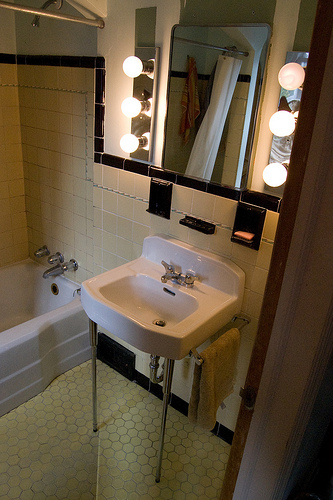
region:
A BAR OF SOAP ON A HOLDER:
[223, 220, 266, 250]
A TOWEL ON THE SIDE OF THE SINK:
[184, 321, 244, 438]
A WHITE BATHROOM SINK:
[75, 229, 263, 371]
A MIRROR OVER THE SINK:
[156, 15, 280, 194]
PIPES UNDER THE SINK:
[140, 349, 184, 389]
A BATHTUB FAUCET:
[26, 240, 84, 286]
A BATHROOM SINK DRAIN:
[148, 312, 170, 329]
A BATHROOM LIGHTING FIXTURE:
[114, 49, 161, 164]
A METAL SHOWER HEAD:
[26, 7, 52, 33]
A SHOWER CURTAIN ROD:
[4, 3, 113, 33]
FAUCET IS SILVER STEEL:
[153, 252, 207, 310]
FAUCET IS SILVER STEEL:
[146, 260, 194, 297]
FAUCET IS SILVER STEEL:
[150, 251, 202, 302]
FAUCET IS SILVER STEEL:
[141, 256, 219, 323]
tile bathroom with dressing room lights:
[5, 0, 327, 490]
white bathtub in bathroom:
[0, 248, 101, 417]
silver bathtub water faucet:
[26, 243, 84, 288]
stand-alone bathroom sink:
[79, 228, 255, 486]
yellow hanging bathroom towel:
[170, 312, 258, 468]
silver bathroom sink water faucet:
[155, 254, 200, 296]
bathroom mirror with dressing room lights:
[125, 8, 303, 203]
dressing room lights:
[117, 42, 319, 195]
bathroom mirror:
[152, 1, 275, 201]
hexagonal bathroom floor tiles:
[6, 419, 144, 497]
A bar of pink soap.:
[237, 227, 250, 244]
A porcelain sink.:
[79, 235, 232, 347]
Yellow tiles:
[45, 435, 101, 483]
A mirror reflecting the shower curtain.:
[174, 33, 252, 193]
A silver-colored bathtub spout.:
[41, 268, 55, 279]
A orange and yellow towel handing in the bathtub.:
[180, 55, 207, 123]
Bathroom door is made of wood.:
[214, 296, 290, 493]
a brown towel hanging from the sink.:
[203, 339, 244, 426]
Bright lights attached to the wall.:
[114, 53, 147, 148]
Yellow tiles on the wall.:
[98, 203, 141, 243]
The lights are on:
[108, 30, 172, 180]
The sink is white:
[103, 282, 196, 335]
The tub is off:
[32, 258, 97, 312]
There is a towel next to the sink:
[187, 329, 290, 454]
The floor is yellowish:
[33, 419, 131, 497]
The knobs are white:
[149, 255, 205, 310]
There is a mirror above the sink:
[170, 76, 284, 254]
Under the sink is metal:
[125, 341, 193, 418]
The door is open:
[222, 310, 308, 486]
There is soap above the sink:
[225, 218, 273, 266]